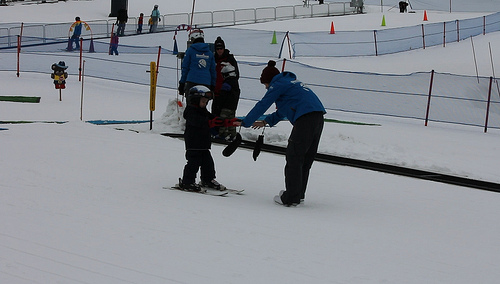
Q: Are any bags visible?
A: No, there are no bags.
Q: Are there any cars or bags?
A: No, there are no bags or cars.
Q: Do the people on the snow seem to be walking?
A: Yes, the people are walking.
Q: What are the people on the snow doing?
A: The people are walking.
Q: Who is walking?
A: The people are walking.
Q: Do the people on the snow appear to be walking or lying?
A: The people are walking.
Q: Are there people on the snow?
A: Yes, there are people on the snow.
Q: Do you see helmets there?
A: Yes, there is a helmet.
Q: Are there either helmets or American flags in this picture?
A: Yes, there is a helmet.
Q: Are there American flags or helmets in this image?
A: Yes, there is a helmet.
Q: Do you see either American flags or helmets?
A: Yes, there is a helmet.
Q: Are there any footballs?
A: No, there are no footballs.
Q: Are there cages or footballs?
A: No, there are no footballs or cages.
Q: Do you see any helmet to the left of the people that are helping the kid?
A: Yes, there is a helmet to the left of the people.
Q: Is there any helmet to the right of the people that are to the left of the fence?
A: No, the helmet is to the left of the people.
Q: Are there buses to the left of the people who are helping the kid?
A: No, there is a helmet to the left of the people.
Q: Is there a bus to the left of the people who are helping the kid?
A: No, there is a helmet to the left of the people.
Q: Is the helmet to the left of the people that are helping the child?
A: Yes, the helmet is to the left of the people.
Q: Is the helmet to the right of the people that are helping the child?
A: No, the helmet is to the left of the people.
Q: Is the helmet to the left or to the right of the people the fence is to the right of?
A: The helmet is to the left of the people.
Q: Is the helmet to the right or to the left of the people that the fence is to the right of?
A: The helmet is to the left of the people.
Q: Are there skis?
A: Yes, there are skis.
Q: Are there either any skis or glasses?
A: Yes, there are skis.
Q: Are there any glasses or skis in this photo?
A: Yes, there are skis.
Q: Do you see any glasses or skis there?
A: Yes, there are skis.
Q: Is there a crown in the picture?
A: No, there are no crowns.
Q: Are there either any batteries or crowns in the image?
A: No, there are no crowns or batteries.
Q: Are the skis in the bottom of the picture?
A: Yes, the skis are in the bottom of the image.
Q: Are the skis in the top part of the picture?
A: No, the skis are in the bottom of the image.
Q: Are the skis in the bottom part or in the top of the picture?
A: The skis are in the bottom of the image.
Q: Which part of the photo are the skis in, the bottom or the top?
A: The skis are in the bottom of the image.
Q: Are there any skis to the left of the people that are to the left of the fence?
A: Yes, there are skis to the left of the people.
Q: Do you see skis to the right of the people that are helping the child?
A: No, the skis are to the left of the people.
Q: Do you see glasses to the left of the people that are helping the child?
A: No, there are skis to the left of the people.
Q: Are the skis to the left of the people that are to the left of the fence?
A: Yes, the skis are to the left of the people.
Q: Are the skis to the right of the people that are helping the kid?
A: No, the skis are to the left of the people.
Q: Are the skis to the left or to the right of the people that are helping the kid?
A: The skis are to the left of the people.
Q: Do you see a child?
A: Yes, there is a child.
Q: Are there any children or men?
A: Yes, there is a child.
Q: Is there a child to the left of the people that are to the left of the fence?
A: Yes, there is a child to the left of the people.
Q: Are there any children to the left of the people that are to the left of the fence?
A: Yes, there is a child to the left of the people.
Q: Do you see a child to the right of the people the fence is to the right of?
A: No, the child is to the left of the people.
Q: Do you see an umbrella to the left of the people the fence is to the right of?
A: No, there is a child to the left of the people.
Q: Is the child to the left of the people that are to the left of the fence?
A: Yes, the child is to the left of the people.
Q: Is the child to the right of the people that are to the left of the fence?
A: No, the child is to the left of the people.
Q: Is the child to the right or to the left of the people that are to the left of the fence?
A: The child is to the left of the people.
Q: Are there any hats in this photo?
A: Yes, there is a hat.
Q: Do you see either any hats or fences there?
A: Yes, there is a hat.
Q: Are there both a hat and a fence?
A: Yes, there are both a hat and a fence.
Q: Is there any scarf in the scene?
A: No, there are no scarves.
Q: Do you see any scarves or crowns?
A: No, there are no scarves or crowns.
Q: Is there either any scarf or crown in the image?
A: No, there are no scarves or crowns.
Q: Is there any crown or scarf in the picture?
A: No, there are no scarves or crowns.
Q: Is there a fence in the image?
A: Yes, there is a fence.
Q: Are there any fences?
A: Yes, there is a fence.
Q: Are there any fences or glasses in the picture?
A: Yes, there is a fence.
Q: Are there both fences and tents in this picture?
A: No, there is a fence but no tents.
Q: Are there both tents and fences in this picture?
A: No, there is a fence but no tents.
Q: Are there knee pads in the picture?
A: No, there are no knee pads.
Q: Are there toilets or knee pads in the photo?
A: No, there are no knee pads or toilets.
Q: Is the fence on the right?
A: Yes, the fence is on the right of the image.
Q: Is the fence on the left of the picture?
A: No, the fence is on the right of the image.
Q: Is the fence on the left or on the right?
A: The fence is on the right of the image.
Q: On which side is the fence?
A: The fence is on the right of the image.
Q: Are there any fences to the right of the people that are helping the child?
A: Yes, there is a fence to the right of the people.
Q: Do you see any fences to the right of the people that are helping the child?
A: Yes, there is a fence to the right of the people.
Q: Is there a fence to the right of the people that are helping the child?
A: Yes, there is a fence to the right of the people.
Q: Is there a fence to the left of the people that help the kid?
A: No, the fence is to the right of the people.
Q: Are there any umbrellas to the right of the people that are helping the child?
A: No, there is a fence to the right of the people.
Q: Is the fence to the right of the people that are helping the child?
A: Yes, the fence is to the right of the people.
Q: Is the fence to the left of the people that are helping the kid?
A: No, the fence is to the right of the people.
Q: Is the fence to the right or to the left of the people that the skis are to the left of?
A: The fence is to the right of the people.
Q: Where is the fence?
A: The fence is on the snow.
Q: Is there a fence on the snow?
A: Yes, there is a fence on the snow.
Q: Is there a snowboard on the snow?
A: No, there is a fence on the snow.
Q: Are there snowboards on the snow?
A: No, there is a fence on the snow.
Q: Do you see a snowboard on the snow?
A: No, there is a fence on the snow.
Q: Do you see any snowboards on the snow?
A: No, there is a fence on the snow.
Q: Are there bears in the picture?
A: Yes, there is a bear.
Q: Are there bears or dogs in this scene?
A: Yes, there is a bear.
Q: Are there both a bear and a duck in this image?
A: No, there is a bear but no ducks.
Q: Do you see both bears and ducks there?
A: No, there is a bear but no ducks.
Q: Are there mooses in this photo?
A: No, there are no mooses.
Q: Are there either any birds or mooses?
A: No, there are no mooses or birds.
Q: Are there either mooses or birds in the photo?
A: No, there are no mooses or birds.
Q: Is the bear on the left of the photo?
A: Yes, the bear is on the left of the image.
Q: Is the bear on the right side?
A: No, the bear is on the left of the image.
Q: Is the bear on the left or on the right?
A: The bear is on the left of the image.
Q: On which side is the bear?
A: The bear is on the left of the image.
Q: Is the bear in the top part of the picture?
A: Yes, the bear is in the top of the image.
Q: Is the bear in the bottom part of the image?
A: No, the bear is in the top of the image.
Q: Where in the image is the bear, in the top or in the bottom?
A: The bear is in the top of the image.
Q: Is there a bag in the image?
A: No, there are no bags.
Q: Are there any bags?
A: No, there are no bags.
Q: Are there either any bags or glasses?
A: No, there are no bags or glasses.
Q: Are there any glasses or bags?
A: No, there are no bags or glasses.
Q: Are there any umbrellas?
A: No, there are no umbrellas.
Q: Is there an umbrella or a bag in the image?
A: No, there are no umbrellas or bags.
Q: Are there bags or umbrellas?
A: No, there are no umbrellas or bags.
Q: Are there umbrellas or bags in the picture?
A: No, there are no umbrellas or bags.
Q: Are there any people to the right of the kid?
A: Yes, there are people to the right of the kid.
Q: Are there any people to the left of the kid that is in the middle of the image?
A: No, the people are to the right of the child.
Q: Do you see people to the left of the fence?
A: Yes, there are people to the left of the fence.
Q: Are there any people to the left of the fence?
A: Yes, there are people to the left of the fence.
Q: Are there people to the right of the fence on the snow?
A: No, the people are to the left of the fence.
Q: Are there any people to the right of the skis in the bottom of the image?
A: Yes, there are people to the right of the skis.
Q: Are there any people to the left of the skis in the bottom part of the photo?
A: No, the people are to the right of the skis.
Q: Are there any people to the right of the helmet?
A: Yes, there are people to the right of the helmet.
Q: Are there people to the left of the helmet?
A: No, the people are to the right of the helmet.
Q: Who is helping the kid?
A: The people are helping the kid.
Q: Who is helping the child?
A: The people are helping the kid.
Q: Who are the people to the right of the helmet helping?
A: The people are helping the kid.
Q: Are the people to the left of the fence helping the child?
A: Yes, the people are helping the child.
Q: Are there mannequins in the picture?
A: No, there are no mannequins.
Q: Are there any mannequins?
A: No, there are no mannequins.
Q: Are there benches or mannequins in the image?
A: No, there are no mannequins or benches.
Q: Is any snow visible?
A: Yes, there is snow.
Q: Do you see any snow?
A: Yes, there is snow.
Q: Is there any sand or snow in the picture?
A: Yes, there is snow.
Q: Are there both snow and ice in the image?
A: No, there is snow but no ice.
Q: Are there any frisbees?
A: No, there are no frisbees.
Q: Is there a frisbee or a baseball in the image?
A: No, there are no frisbees or baseballs.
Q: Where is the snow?
A: The snow is on the ground.